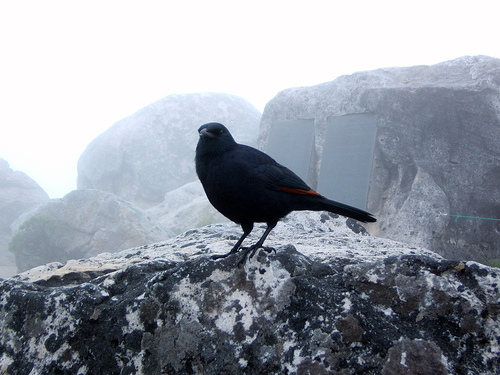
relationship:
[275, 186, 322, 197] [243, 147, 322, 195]
feather under wing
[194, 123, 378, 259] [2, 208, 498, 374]
bird perched on rock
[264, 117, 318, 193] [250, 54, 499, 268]
plaque mounted in mountain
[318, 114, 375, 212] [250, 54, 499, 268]
plaque mounted in mountain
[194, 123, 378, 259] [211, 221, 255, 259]
bird has leg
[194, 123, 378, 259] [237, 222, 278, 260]
bird has leg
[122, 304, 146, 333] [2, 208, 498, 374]
white patch located on rock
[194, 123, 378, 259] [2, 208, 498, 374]
bird on top of rock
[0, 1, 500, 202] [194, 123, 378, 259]
sky above bird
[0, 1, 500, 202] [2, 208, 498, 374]
sky above rock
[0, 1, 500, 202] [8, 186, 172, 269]
sky above boulder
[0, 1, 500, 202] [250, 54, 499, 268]
sky above mountain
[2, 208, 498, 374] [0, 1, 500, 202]
rock under sky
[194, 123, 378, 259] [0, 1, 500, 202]
bird under sky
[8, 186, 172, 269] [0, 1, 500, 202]
boulder under sky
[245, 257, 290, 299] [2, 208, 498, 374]
white patch located on rock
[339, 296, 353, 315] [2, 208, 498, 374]
white patch located on rock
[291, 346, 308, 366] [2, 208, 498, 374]
white patch located on rock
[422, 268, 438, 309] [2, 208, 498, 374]
white patch located on rock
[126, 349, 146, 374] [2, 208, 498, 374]
white patch located on rock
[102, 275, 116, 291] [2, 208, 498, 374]
white patch located on rock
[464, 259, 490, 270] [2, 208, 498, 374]
white patch located on rock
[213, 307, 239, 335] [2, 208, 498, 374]
white patch located on rock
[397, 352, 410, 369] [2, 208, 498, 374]
white patch located on rock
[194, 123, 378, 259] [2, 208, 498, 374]
bird sitting on rock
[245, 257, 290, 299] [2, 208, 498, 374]
white patch visible on rock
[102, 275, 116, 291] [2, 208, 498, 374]
white patch visible on rock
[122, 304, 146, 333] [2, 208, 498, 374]
white patch visible on rock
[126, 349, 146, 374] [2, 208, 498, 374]
white patch visible on rock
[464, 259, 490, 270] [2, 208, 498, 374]
white patch visible on rock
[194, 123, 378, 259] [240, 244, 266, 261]
bird has foot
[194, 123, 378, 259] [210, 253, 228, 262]
bird has foot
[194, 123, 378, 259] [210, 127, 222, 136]
bird has eye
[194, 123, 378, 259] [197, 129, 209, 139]
bird has beak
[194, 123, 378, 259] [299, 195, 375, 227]
bird has tail feathers